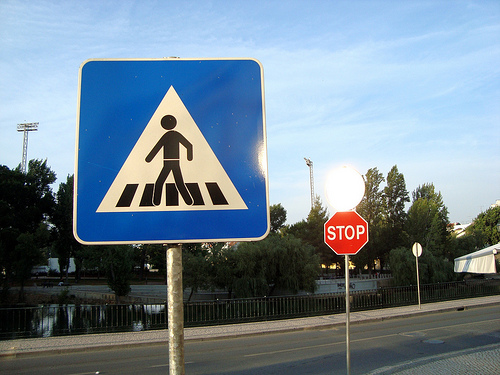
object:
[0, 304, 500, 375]
road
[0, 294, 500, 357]
sidewalk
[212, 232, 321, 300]
tree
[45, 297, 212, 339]
water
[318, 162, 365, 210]
white light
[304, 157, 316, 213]
tower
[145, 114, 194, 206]
figure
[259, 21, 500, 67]
clouds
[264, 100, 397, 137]
clouds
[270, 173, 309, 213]
clouds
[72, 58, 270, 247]
sign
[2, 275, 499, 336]
railing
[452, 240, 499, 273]
canopy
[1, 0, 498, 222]
sky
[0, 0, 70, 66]
clouds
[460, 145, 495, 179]
white cloud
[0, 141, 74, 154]
white cloud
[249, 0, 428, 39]
blue sky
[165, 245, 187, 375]
pole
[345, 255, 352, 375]
pole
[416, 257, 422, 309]
pole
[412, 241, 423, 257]
sign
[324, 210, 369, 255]
sign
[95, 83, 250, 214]
triangle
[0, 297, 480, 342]
lake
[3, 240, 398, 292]
town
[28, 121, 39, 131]
lights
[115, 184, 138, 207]
crossing strip